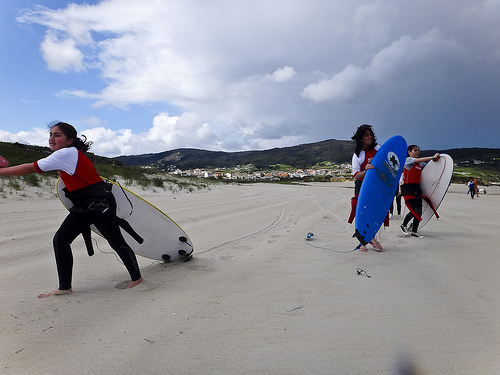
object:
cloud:
[0, 0, 499, 169]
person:
[1, 117, 146, 299]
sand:
[1, 177, 500, 374]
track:
[193, 197, 295, 256]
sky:
[0, 1, 499, 159]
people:
[0, 118, 145, 299]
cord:
[301, 230, 365, 254]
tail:
[71, 134, 94, 155]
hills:
[107, 137, 356, 182]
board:
[55, 175, 194, 264]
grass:
[448, 165, 499, 186]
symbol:
[387, 149, 401, 172]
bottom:
[352, 228, 369, 246]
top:
[385, 134, 410, 150]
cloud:
[0, 0, 499, 159]